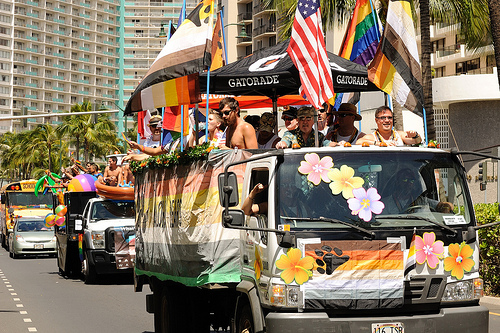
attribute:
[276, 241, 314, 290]
flower — orange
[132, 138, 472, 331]
truck — open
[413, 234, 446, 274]
flower — pink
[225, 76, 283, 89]
writing — white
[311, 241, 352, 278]
paw print — black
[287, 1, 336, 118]
flag — american, large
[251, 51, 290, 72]
symbol — white, orange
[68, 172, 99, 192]
ball — colorful, large, multi-colored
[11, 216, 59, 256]
car — gray, compact, silver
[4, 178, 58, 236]
school bus — yellow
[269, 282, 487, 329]
grill — black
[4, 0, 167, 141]
complex — large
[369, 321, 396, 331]
license plate — white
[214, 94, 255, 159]
man — shirtless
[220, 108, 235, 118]
glasses — dark, black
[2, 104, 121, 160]
cluster — large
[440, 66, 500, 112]
balcony — white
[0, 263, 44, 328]
lines — white, broken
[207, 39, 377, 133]
tent — black, white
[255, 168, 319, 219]
passenger — man